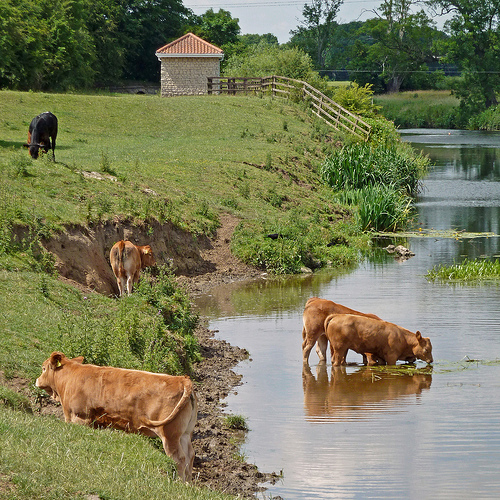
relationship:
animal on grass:
[11, 102, 63, 161] [101, 117, 194, 177]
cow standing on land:
[25, 343, 176, 440] [12, 191, 290, 493]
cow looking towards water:
[112, 229, 164, 281] [368, 247, 489, 324]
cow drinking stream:
[323, 313, 433, 367] [385, 293, 467, 331]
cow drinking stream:
[300, 299, 386, 366] [385, 293, 467, 331]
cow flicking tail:
[34, 352, 197, 483] [138, 377, 193, 429]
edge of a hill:
[218, 82, 421, 272] [122, 93, 350, 269]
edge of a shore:
[161, 125, 421, 273] [222, 52, 474, 372]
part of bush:
[426, 273, 436, 283] [420, 274, 440, 284]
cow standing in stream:
[326, 313, 433, 376] [193, 128, 500, 497]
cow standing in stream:
[300, 295, 383, 372] [193, 128, 500, 497]